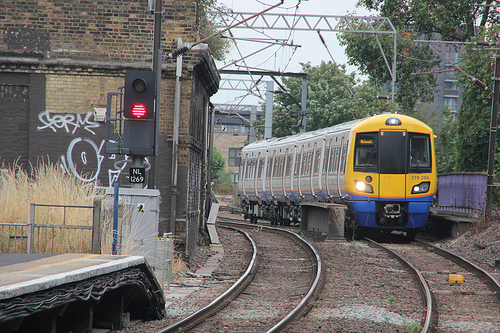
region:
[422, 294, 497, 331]
the train tracks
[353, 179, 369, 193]
the headlight on the train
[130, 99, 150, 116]
red light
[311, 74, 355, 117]
a green bush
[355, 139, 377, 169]
a windshield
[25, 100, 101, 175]
tagging on the wall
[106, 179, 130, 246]
a blue pole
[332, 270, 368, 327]
rocks on the ground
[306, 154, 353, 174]
windows on the train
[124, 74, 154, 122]
traffic signal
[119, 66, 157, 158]
A stoplight with red light highlighted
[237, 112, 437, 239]
A train engine on the track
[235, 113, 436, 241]
A train with a yellow and blue face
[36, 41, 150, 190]
Graffiti on the side of the building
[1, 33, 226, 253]
A building made of different types of bricks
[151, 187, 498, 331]
Train tracks curving around the building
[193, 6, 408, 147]
Scaffolding high above a train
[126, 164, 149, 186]
A sign with NL 1269 on it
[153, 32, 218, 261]
Pipes running vertical on the side of a building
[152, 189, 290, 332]
Broken cement next to train tracks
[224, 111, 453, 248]
train on the track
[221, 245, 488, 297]
tracks trains travel on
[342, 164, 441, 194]
lights on the train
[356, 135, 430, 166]
windows on the train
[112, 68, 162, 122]
lights near the track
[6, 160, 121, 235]
plants near the track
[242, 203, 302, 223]
wheels on the train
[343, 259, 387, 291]
rocks on the track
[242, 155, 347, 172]
windows on the train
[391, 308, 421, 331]
grass on the track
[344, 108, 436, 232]
Front end on a yellow train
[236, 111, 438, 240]
Yellow train coming down the track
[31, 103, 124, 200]
Graffiti on the side of a building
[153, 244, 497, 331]
Railroad tracks in the dirt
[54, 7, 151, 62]
Brick wall of an old building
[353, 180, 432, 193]
Headlights on a yellow train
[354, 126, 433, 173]
Front windows on a yellow train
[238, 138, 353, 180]
Windows on the side of a train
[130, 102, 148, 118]
A glowing, red light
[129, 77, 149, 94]
A dimmed traffic light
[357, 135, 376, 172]
window of a train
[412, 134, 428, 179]
window of a train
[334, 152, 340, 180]
window of a train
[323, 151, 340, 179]
window of a train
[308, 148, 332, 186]
window of a train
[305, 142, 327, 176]
window of a train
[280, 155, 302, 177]
window of a train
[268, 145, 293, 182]
window of a train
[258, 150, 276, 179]
window of a train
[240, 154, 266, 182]
window of a train